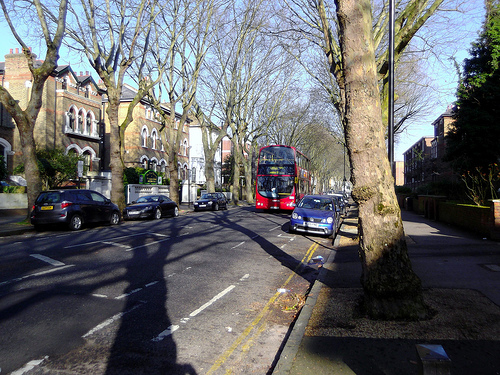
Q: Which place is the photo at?
A: It is at the road.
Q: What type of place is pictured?
A: It is a road.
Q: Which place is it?
A: It is a road.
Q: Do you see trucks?
A: No, there are no trucks.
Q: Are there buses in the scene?
A: Yes, there is a bus.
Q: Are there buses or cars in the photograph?
A: Yes, there is a bus.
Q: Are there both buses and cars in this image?
A: Yes, there are both a bus and a car.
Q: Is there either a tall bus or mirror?
A: Yes, there is a tall bus.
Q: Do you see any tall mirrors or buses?
A: Yes, there is a tall bus.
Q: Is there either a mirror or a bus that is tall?
A: Yes, the bus is tall.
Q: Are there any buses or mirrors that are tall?
A: Yes, the bus is tall.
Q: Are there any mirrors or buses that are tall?
A: Yes, the bus is tall.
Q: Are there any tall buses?
A: Yes, there is a tall bus.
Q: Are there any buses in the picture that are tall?
A: Yes, there is a bus that is tall.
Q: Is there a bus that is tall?
A: Yes, there is a bus that is tall.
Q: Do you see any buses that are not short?
A: Yes, there is a tall bus.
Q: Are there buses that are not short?
A: Yes, there is a tall bus.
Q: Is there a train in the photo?
A: No, there are no trains.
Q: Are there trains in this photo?
A: No, there are no trains.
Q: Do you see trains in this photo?
A: No, there are no trains.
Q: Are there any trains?
A: No, there are no trains.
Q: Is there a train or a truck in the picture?
A: No, there are no trains or trucks.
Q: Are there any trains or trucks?
A: No, there are no trains or trucks.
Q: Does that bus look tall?
A: Yes, the bus is tall.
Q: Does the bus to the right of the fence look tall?
A: Yes, the bus is tall.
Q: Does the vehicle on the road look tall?
A: Yes, the bus is tall.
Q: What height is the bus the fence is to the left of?
A: The bus is tall.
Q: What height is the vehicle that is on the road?
A: The bus is tall.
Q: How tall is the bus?
A: The bus is tall.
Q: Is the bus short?
A: No, the bus is tall.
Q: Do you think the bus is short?
A: No, the bus is tall.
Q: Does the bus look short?
A: No, the bus is tall.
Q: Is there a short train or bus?
A: No, there is a bus but it is tall.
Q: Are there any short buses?
A: No, there is a bus but it is tall.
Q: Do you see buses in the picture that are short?
A: No, there is a bus but it is tall.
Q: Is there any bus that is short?
A: No, there is a bus but it is tall.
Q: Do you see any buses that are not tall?
A: No, there is a bus but it is tall.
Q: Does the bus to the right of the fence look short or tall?
A: The bus is tall.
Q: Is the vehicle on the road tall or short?
A: The bus is tall.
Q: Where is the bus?
A: The bus is on the road.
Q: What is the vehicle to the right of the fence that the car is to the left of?
A: The vehicle is a bus.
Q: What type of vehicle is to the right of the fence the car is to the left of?
A: The vehicle is a bus.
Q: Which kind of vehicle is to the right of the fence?
A: The vehicle is a bus.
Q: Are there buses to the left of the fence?
A: No, the bus is to the right of the fence.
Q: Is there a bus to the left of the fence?
A: No, the bus is to the right of the fence.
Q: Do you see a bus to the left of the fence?
A: No, the bus is to the right of the fence.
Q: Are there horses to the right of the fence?
A: No, there is a bus to the right of the fence.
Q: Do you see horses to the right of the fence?
A: No, there is a bus to the right of the fence.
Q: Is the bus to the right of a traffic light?
A: No, the bus is to the right of the fence.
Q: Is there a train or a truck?
A: No, there are no trucks or trains.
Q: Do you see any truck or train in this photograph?
A: No, there are no trucks or trains.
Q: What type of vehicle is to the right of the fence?
A: The vehicle is a car.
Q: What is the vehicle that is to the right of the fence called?
A: The vehicle is a car.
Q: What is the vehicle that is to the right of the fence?
A: The vehicle is a car.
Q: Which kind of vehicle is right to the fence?
A: The vehicle is a car.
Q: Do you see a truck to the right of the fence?
A: No, there is a car to the right of the fence.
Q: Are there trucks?
A: No, there are no trucks.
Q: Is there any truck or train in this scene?
A: No, there are no trucks or trains.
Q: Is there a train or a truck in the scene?
A: No, there are no trucks or trains.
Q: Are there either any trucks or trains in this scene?
A: No, there are no trucks or trains.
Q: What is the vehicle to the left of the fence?
A: The vehicle is a car.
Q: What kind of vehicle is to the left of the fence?
A: The vehicle is a car.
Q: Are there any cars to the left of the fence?
A: Yes, there is a car to the left of the fence.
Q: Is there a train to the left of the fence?
A: No, there is a car to the left of the fence.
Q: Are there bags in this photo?
A: No, there are no bags.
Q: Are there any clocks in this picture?
A: No, there are no clocks.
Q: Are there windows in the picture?
A: Yes, there is a window.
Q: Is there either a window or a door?
A: Yes, there is a window.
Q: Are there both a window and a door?
A: No, there is a window but no doors.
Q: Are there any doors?
A: No, there are no doors.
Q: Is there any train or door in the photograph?
A: No, there are no doors or trains.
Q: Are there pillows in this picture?
A: No, there are no pillows.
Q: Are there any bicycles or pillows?
A: No, there are no pillows or bicycles.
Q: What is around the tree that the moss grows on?
A: The gravel is around the tree.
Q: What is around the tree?
A: The gravel is around the tree.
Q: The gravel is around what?
A: The gravel is around the tree.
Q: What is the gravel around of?
A: The gravel is around the tree.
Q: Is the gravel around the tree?
A: Yes, the gravel is around the tree.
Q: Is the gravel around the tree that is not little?
A: Yes, the gravel is around the tree.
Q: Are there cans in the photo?
A: No, there are no cans.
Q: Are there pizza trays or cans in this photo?
A: No, there are no cans or pizza trays.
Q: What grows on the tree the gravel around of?
A: The moss grows on the tree.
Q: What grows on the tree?
A: The moss grows on the tree.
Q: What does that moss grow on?
A: The moss grows on the tree.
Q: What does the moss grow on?
A: The moss grows on the tree.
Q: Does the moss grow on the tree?
A: Yes, the moss grows on the tree.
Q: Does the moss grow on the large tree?
A: Yes, the moss grows on the tree.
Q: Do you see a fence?
A: Yes, there is a fence.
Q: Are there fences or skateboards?
A: Yes, there is a fence.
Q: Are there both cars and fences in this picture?
A: Yes, there are both a fence and a car.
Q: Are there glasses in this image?
A: No, there are no glasses.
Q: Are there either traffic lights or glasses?
A: No, there are no glasses or traffic lights.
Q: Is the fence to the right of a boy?
A: No, the fence is to the right of a car.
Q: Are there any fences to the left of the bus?
A: Yes, there is a fence to the left of the bus.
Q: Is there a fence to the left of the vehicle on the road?
A: Yes, there is a fence to the left of the bus.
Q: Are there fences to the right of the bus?
A: No, the fence is to the left of the bus.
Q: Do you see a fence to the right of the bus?
A: No, the fence is to the left of the bus.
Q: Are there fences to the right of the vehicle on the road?
A: No, the fence is to the left of the bus.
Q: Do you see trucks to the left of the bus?
A: No, there is a fence to the left of the bus.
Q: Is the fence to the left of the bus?
A: Yes, the fence is to the left of the bus.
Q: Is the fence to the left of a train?
A: No, the fence is to the left of the bus.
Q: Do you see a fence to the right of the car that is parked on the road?
A: No, the fence is to the left of the car.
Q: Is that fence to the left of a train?
A: No, the fence is to the left of the car.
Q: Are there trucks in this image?
A: No, there are no trucks.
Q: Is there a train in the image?
A: No, there are no trains.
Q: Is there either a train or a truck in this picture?
A: No, there are no trains or trucks.